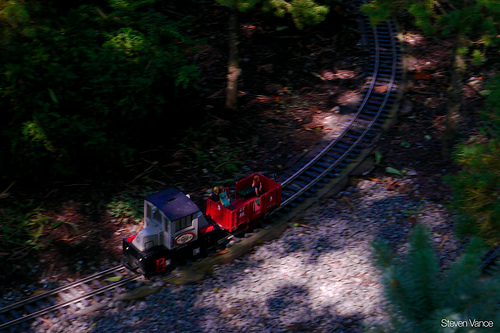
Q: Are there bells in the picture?
A: No, there are no bells.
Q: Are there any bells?
A: No, there are no bells.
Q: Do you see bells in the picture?
A: No, there are no bells.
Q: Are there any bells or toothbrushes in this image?
A: No, there are no bells or toothbrushes.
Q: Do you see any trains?
A: Yes, there is a train.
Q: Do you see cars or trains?
A: Yes, there is a train.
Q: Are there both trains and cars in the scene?
A: Yes, there are both a train and a car.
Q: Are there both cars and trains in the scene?
A: Yes, there are both a train and a car.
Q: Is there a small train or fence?
A: Yes, there is a small train.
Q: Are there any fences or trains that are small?
A: Yes, the train is small.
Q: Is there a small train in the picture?
A: Yes, there is a small train.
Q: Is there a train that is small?
A: Yes, there is a train that is small.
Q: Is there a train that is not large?
A: Yes, there is a small train.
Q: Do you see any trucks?
A: No, there are no trucks.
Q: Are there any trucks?
A: No, there are no trucks.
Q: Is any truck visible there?
A: No, there are no trucks.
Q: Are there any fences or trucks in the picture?
A: No, there are no trucks or fences.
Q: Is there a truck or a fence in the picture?
A: No, there are no trucks or fences.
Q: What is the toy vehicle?
A: The vehicle is a train.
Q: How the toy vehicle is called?
A: The vehicle is a train.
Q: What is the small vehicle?
A: The vehicle is a train.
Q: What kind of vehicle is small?
A: The vehicle is a train.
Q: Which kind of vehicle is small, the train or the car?
A: The train is small.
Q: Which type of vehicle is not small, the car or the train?
A: The car is not small.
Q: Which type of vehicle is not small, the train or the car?
A: The car is not small.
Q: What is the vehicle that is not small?
A: The vehicle is a car.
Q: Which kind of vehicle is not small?
A: The vehicle is a car.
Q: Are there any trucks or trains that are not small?
A: No, there is a train but it is small.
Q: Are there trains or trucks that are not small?
A: No, there is a train but it is small.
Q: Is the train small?
A: Yes, the train is small.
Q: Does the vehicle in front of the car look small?
A: Yes, the train is small.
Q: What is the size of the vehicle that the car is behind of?
A: The train is small.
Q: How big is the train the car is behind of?
A: The train is small.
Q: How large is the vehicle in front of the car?
A: The train is small.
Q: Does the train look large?
A: No, the train is small.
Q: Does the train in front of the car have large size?
A: No, the train is small.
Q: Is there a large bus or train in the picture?
A: No, there is a train but it is small.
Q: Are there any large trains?
A: No, there is a train but it is small.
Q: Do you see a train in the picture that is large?
A: No, there is a train but it is small.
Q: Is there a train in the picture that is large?
A: No, there is a train but it is small.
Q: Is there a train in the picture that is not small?
A: No, there is a train but it is small.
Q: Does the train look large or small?
A: The train is small.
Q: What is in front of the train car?
A: The train is in front of the car.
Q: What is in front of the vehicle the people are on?
A: The train is in front of the car.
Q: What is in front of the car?
A: The train is in front of the car.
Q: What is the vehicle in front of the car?
A: The vehicle is a train.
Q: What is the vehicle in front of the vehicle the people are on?
A: The vehicle is a train.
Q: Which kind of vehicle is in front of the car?
A: The vehicle is a train.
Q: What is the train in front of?
A: The train is in front of the car.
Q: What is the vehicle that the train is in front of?
A: The vehicle is a car.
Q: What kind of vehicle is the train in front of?
A: The train is in front of the car.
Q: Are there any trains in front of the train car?
A: Yes, there is a train in front of the car.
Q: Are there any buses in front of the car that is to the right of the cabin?
A: No, there is a train in front of the car.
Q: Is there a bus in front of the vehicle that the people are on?
A: No, there is a train in front of the car.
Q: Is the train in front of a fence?
A: No, the train is in front of the car.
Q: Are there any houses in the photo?
A: No, there are no houses.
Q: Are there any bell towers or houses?
A: No, there are no houses or bell towers.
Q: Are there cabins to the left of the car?
A: Yes, there is a cabin to the left of the car.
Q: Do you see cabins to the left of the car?
A: Yes, there is a cabin to the left of the car.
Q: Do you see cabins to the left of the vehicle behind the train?
A: Yes, there is a cabin to the left of the car.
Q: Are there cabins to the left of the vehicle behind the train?
A: Yes, there is a cabin to the left of the car.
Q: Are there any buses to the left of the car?
A: No, there is a cabin to the left of the car.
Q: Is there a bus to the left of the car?
A: No, there is a cabin to the left of the car.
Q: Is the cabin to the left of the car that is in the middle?
A: Yes, the cabin is to the left of the car.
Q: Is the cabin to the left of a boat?
A: No, the cabin is to the left of the car.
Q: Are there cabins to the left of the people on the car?
A: Yes, there is a cabin to the left of the people.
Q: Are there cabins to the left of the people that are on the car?
A: Yes, there is a cabin to the left of the people.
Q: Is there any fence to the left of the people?
A: No, there is a cabin to the left of the people.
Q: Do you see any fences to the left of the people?
A: No, there is a cabin to the left of the people.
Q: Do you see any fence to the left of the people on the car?
A: No, there is a cabin to the left of the people.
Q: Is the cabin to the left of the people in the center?
A: Yes, the cabin is to the left of the people.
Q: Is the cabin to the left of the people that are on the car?
A: Yes, the cabin is to the left of the people.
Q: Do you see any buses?
A: No, there are no buses.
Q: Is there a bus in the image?
A: No, there are no buses.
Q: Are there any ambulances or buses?
A: No, there are no buses or ambulances.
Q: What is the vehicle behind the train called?
A: The vehicle is a car.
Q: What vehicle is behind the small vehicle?
A: The vehicle is a car.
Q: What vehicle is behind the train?
A: The vehicle is a car.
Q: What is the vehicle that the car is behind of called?
A: The vehicle is a train.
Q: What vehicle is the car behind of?
A: The car is behind the train.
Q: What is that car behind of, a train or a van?
A: The car is behind a train.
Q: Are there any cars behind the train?
A: Yes, there is a car behind the train.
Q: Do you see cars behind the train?
A: Yes, there is a car behind the train.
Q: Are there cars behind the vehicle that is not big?
A: Yes, there is a car behind the train.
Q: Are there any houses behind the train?
A: No, there is a car behind the train.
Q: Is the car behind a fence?
A: No, the car is behind the train.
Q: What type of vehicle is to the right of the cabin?
A: The vehicle is a car.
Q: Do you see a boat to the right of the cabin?
A: No, there is a car to the right of the cabin.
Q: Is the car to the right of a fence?
A: No, the car is to the right of the cabin.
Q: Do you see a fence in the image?
A: No, there are no fences.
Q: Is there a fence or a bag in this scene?
A: No, there are no fences or bags.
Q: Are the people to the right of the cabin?
A: Yes, the people are to the right of the cabin.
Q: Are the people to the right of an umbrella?
A: No, the people are to the right of the cabin.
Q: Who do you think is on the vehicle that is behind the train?
A: The people are on the car.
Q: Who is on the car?
A: The people are on the car.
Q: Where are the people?
A: The people are on the car.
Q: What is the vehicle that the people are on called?
A: The vehicle is a car.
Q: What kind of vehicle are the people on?
A: The people are on the car.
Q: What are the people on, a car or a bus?
A: The people are on a car.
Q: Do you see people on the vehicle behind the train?
A: Yes, there are people on the car.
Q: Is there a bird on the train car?
A: No, there are people on the car.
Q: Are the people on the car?
A: Yes, the people are on the car.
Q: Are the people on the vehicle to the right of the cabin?
A: Yes, the people are on the car.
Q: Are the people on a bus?
A: No, the people are on the car.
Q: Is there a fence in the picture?
A: No, there are no fences.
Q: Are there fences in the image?
A: No, there are no fences.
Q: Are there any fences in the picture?
A: No, there are no fences.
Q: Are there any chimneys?
A: No, there are no chimneys.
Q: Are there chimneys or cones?
A: No, there are no chimneys or cones.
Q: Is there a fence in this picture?
A: No, there are no fences.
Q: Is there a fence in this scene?
A: No, there are no fences.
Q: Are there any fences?
A: No, there are no fences.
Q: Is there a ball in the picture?
A: No, there are no balls.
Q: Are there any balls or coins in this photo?
A: No, there are no balls or coins.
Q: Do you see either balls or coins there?
A: No, there are no balls or coins.